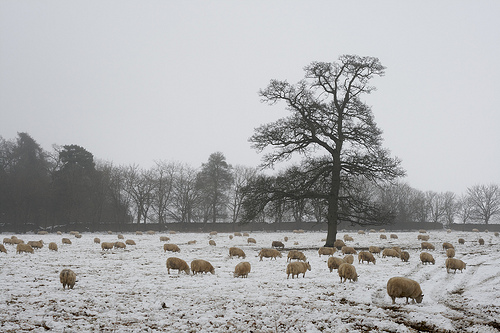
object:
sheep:
[234, 261, 251, 280]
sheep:
[166, 257, 190, 276]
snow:
[0, 231, 500, 332]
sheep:
[285, 261, 312, 280]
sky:
[0, 0, 500, 224]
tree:
[235, 54, 406, 248]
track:
[371, 261, 424, 305]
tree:
[52, 142, 110, 232]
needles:
[70, 185, 77, 191]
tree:
[145, 160, 184, 223]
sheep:
[445, 258, 466, 274]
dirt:
[410, 321, 428, 330]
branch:
[334, 64, 345, 108]